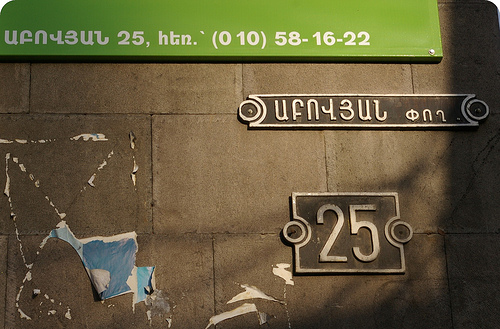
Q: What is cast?
A: Shadow.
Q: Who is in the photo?
A: No one.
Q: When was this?
A: Daytime.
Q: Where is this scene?
A: Street.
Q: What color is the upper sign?
A: Green.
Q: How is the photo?
A: Clear.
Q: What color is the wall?
A: Brown.